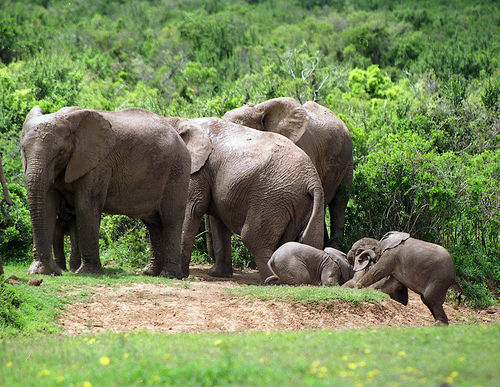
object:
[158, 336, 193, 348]
grass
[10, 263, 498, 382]
field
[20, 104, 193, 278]
elephant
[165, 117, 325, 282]
elephant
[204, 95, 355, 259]
elephant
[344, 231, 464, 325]
elephant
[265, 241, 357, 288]
elephant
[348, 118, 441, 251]
tree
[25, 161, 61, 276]
trunk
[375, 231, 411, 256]
ear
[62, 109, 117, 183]
ear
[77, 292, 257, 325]
dirt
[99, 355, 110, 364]
flower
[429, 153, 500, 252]
bush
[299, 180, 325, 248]
tail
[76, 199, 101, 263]
leg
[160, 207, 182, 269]
leg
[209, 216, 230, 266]
leg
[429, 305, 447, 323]
leg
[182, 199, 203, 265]
leg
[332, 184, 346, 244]
leg